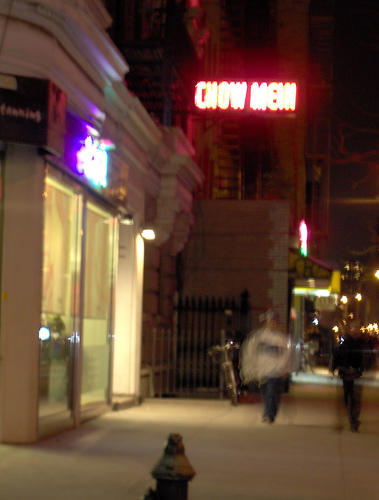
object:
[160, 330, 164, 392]
pole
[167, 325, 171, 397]
pole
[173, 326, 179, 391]
pole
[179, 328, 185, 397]
pole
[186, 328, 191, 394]
pole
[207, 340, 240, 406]
bicycle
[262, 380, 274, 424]
leg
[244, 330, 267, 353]
arm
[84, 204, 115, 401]
windows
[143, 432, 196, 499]
fire hydrant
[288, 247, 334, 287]
awning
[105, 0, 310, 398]
building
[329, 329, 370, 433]
person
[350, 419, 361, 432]
feet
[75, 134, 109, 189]
lighted sign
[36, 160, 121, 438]
doorway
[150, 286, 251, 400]
iron fence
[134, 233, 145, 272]
glowing light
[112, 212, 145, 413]
over doorway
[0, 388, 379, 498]
sidewalk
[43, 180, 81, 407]
window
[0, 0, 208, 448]
business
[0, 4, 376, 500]
night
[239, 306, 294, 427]
person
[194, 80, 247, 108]
word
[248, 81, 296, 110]
word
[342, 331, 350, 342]
head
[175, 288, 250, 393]
black fence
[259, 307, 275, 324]
head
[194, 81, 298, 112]
chow mein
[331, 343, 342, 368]
arm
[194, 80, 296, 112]
sign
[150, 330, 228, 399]
fence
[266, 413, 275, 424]
feet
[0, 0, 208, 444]
building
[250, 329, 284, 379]
shirt